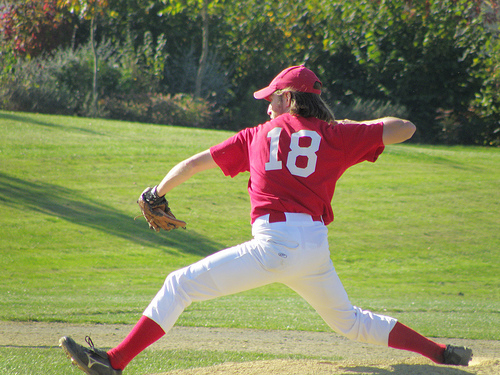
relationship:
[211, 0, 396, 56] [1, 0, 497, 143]
leaves on trees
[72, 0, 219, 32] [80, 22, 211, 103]
leaves on tree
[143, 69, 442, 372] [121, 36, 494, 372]
uniform on player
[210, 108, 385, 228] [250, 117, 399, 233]
t-shirt labeled eighteen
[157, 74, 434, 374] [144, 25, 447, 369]
man throwing baseball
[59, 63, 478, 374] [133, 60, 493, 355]
man in pitching stance